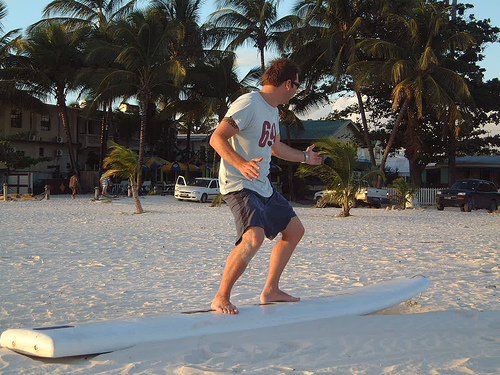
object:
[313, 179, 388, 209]
truck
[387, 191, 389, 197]
taillights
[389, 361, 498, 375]
sand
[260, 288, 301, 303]
barefoot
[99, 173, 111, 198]
person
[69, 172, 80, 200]
people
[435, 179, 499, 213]
car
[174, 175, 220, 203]
car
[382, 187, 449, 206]
fence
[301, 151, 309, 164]
watch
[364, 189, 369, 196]
lights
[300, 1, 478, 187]
trees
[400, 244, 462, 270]
sand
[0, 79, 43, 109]
roof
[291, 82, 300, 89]
sunglasses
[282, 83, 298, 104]
face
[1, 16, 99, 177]
palms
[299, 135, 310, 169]
wrist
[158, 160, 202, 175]
umbrellas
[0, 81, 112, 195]
house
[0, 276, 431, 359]
surfboard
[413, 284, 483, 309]
sand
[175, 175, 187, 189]
door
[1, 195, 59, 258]
sand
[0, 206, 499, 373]
beach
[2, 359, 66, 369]
sand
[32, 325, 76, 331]
design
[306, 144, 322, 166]
hand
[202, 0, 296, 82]
tree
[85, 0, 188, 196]
tree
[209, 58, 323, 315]
man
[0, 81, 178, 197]
building